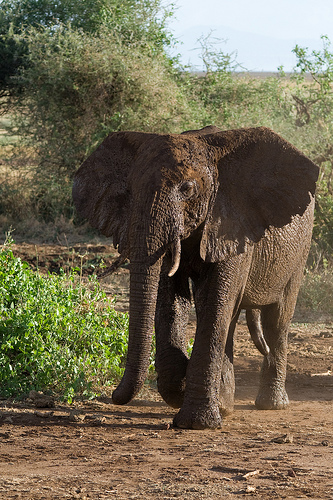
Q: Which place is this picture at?
A: It is at the forest.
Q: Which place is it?
A: It is a forest.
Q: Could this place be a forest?
A: Yes, it is a forest.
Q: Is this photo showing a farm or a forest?
A: It is showing a forest.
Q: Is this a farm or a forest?
A: It is a forest.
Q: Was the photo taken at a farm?
A: No, the picture was taken in a forest.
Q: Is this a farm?
A: No, it is a forest.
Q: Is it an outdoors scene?
A: Yes, it is outdoors.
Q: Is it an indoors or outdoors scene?
A: It is outdoors.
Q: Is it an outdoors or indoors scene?
A: It is outdoors.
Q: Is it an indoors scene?
A: No, it is outdoors.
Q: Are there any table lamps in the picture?
A: No, there are no table lamps.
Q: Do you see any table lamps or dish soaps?
A: No, there are no table lamps or dish soaps.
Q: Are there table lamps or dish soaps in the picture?
A: No, there are no table lamps or dish soaps.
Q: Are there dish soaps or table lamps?
A: No, there are no table lamps or dish soaps.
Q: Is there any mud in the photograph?
A: Yes, there is mud.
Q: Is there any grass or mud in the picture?
A: Yes, there is mud.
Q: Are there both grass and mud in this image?
A: Yes, there are both mud and grass.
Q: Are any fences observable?
A: No, there are no fences.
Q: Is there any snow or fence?
A: No, there are no fences or snow.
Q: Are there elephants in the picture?
A: Yes, there is an elephant.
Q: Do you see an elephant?
A: Yes, there is an elephant.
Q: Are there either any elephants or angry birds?
A: Yes, there is an elephant.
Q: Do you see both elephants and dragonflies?
A: No, there is an elephant but no dragonflies.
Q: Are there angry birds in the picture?
A: No, there are no angry birds.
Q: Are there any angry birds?
A: No, there are no angry birds.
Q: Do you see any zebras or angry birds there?
A: No, there are no angry birds or zebras.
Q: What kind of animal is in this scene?
A: The animal is an elephant.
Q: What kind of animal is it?
A: The animal is an elephant.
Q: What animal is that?
A: This is an elephant.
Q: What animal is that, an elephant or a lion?
A: This is an elephant.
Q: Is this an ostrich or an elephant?
A: This is an elephant.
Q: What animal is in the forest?
A: The elephant is in the forest.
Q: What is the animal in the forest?
A: The animal is an elephant.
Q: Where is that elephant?
A: The elephant is in the forest.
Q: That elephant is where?
A: The elephant is in the forest.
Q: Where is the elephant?
A: The elephant is in the forest.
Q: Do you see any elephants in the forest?
A: Yes, there is an elephant in the forest.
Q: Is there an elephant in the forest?
A: Yes, there is an elephant in the forest.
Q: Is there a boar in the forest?
A: No, there is an elephant in the forest.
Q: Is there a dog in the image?
A: No, there are no dogs.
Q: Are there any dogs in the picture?
A: No, there are no dogs.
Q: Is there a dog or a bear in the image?
A: No, there are no dogs or bears.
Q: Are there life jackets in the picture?
A: No, there are no life jackets.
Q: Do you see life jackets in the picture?
A: No, there are no life jackets.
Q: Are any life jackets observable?
A: No, there are no life jackets.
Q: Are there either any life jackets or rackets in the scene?
A: No, there are no life jackets or rackets.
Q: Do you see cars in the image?
A: No, there are no cars.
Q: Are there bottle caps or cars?
A: No, there are no cars or bottle caps.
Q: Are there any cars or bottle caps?
A: No, there are no cars or bottle caps.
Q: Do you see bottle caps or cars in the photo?
A: No, there are no cars or bottle caps.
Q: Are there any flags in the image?
A: No, there are no flags.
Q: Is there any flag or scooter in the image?
A: No, there are no flags or scooters.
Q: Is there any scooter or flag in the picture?
A: No, there are no flags or scooters.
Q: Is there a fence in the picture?
A: No, there are no fences.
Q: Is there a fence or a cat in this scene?
A: No, there are no fences or cats.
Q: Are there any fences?
A: No, there are no fences.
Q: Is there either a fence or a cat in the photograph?
A: No, there are no fences or cats.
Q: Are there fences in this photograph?
A: No, there are no fences.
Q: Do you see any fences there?
A: No, there are no fences.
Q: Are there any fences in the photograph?
A: No, there are no fences.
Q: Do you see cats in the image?
A: No, there are no cats.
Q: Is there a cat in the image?
A: No, there are no cats.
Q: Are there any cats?
A: No, there are no cats.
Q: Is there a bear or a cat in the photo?
A: No, there are no cats or bears.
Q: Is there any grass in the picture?
A: Yes, there is grass.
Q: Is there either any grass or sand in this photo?
A: Yes, there is grass.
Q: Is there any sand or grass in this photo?
A: Yes, there is grass.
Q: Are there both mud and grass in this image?
A: Yes, there are both grass and mud.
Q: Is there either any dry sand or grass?
A: Yes, there is dry grass.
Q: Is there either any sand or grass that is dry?
A: Yes, the grass is dry.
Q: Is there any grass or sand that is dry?
A: Yes, the grass is dry.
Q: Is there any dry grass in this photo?
A: Yes, there is dry grass.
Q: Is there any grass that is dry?
A: Yes, there is grass that is dry.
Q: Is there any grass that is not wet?
A: Yes, there is dry grass.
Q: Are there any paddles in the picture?
A: No, there are no paddles.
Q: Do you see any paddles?
A: No, there are no paddles.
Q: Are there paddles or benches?
A: No, there are no paddles or benches.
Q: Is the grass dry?
A: Yes, the grass is dry.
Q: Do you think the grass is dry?
A: Yes, the grass is dry.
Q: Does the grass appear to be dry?
A: Yes, the grass is dry.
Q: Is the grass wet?
A: No, the grass is dry.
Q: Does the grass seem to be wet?
A: No, the grass is dry.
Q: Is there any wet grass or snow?
A: No, there is grass but it is dry.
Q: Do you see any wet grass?
A: No, there is grass but it is dry.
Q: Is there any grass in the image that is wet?
A: No, there is grass but it is dry.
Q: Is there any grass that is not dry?
A: No, there is grass but it is dry.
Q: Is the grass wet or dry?
A: The grass is dry.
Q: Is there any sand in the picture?
A: Yes, there is sand.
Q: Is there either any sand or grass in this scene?
A: Yes, there is sand.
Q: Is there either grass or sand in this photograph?
A: Yes, there is sand.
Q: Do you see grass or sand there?
A: Yes, there is sand.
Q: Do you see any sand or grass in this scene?
A: Yes, there is sand.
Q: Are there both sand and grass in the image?
A: Yes, there are both sand and grass.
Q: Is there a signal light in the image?
A: No, there are no traffic lights.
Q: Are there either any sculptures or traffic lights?
A: No, there are no traffic lights or sculptures.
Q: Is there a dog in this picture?
A: No, there are no dogs.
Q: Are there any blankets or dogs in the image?
A: No, there are no dogs or blankets.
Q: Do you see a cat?
A: No, there are no cats.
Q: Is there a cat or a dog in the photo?
A: No, there are no cats or dogs.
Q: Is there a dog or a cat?
A: No, there are no cats or dogs.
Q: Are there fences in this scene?
A: No, there are no fences.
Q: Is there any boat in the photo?
A: No, there are no boats.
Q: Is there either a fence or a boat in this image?
A: No, there are no boats or fences.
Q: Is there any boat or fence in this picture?
A: No, there are no boats or fences.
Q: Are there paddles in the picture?
A: No, there are no paddles.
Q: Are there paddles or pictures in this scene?
A: No, there are no paddles or pictures.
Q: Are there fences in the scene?
A: No, there are no fences.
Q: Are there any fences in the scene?
A: No, there are no fences.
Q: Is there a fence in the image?
A: No, there are no fences.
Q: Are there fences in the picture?
A: No, there are no fences.